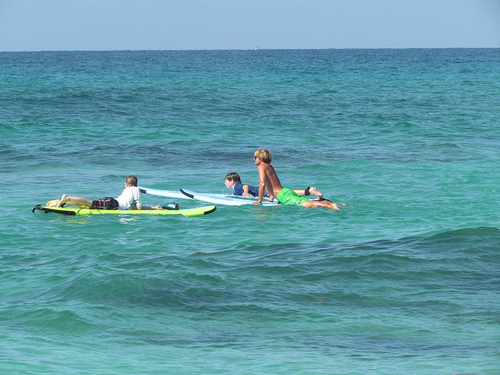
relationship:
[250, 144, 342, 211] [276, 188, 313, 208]
blond wearing shorts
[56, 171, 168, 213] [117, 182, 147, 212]
boy in white shirt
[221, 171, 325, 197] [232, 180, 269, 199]
boy wears blue shirt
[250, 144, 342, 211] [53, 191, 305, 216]
blond on surfboards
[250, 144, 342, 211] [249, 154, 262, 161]
blond wearing sunglasses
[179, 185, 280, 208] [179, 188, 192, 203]
surf board with black tip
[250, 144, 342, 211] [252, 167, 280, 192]
blond bares torso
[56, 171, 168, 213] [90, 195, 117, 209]
boy wears plaid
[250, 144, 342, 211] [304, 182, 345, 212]
blond with bare feet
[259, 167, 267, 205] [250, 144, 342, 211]
arm holds blond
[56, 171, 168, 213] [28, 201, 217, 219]
boy on green board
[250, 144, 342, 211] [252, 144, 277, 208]
surfer sitting up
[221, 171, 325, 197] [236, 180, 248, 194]
boy in blue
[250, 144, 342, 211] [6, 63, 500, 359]
blond in water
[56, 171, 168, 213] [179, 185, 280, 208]
boy on surfboard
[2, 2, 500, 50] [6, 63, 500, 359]
sky over water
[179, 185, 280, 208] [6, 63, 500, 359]
surfboard in water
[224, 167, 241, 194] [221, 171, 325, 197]
head of boy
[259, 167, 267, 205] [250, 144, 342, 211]
arm of boy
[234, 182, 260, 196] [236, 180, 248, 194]
blue shirt of blue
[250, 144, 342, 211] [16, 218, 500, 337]
blond wait for wave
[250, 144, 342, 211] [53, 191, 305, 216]
blond on boards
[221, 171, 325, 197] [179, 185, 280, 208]
boy tied to surfboard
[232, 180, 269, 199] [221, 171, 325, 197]
blue shirt on boy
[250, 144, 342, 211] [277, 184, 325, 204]
boy wearing green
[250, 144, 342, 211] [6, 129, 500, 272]
blond between waves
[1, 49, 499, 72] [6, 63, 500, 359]
darker blue deep water